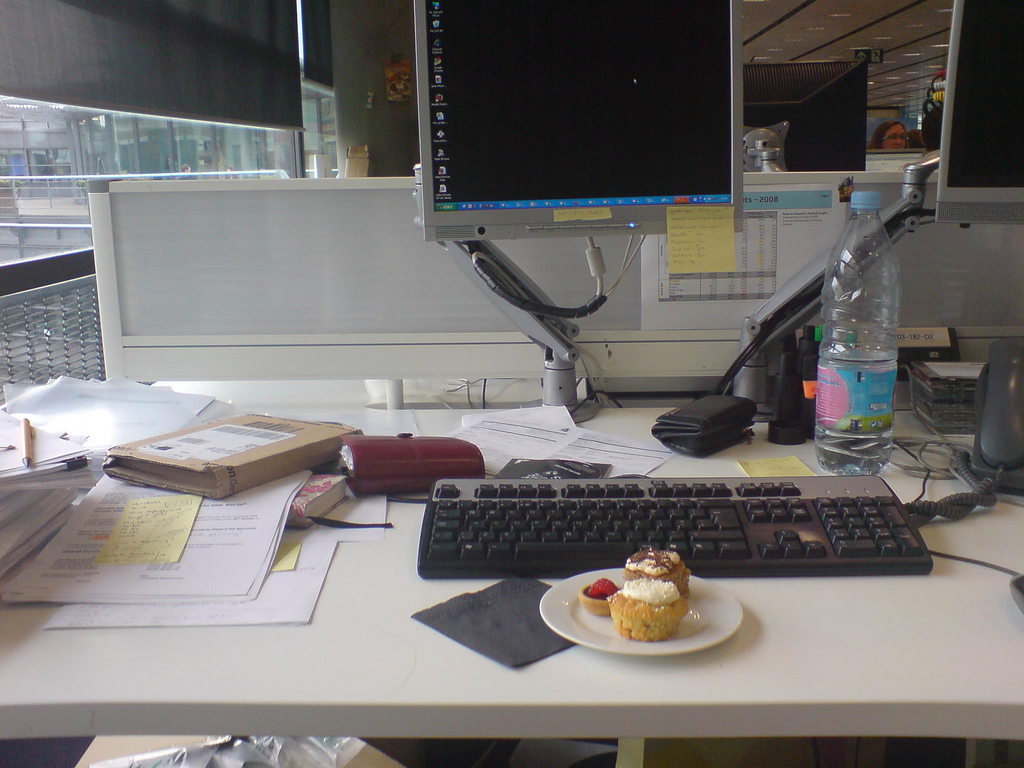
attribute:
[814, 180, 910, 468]
bottle — clear, water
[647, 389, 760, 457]
wallet — black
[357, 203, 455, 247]
monitor — silver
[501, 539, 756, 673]
plate — white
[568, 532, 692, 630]
cupcakes — three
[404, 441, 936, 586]
keyboard — black, silver, computer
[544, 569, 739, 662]
plate — nice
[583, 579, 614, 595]
piece — red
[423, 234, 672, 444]
cords — electrical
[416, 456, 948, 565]
keyboard — black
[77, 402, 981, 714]
office desk — white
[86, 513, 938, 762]
table — white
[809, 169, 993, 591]
bottle — tall, blue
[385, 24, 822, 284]
monitor — displaying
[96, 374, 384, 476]
package — cardboard, labeled